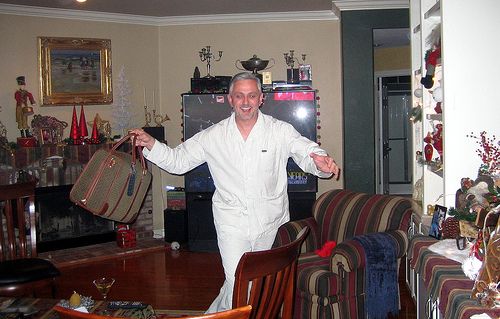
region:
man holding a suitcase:
[73, 73, 343, 226]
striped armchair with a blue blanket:
[315, 193, 410, 317]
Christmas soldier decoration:
[11, 73, 38, 144]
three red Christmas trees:
[70, 103, 100, 146]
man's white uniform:
[215, 145, 282, 220]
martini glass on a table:
[94, 275, 114, 303]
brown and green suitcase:
[77, 134, 150, 222]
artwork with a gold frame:
[39, 37, 112, 102]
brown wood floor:
[138, 254, 209, 297]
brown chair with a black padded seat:
[3, 185, 58, 285]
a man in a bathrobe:
[113, 42, 382, 313]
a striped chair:
[276, 165, 424, 314]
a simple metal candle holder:
[185, 28, 242, 90]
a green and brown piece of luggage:
[61, 106, 188, 248]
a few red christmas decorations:
[66, 98, 110, 153]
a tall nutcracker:
[6, 67, 51, 158]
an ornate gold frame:
[24, 24, 121, 124]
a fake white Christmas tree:
[98, 42, 150, 147]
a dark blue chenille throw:
[328, 213, 420, 313]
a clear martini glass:
[84, 256, 126, 301]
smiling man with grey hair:
[163, 68, 319, 290]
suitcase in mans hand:
[81, 116, 166, 229]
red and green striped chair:
[285, 170, 424, 317]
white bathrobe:
[171, 108, 326, 258]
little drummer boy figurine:
[12, 76, 47, 142]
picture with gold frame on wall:
[29, 31, 129, 125]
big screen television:
[175, 84, 345, 195]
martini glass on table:
[87, 266, 144, 306]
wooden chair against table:
[226, 233, 296, 315]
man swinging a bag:
[59, 48, 358, 295]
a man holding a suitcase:
[67, 70, 342, 265]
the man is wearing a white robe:
[126, 74, 335, 315]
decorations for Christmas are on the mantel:
[5, 70, 167, 150]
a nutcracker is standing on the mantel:
[11, 74, 37, 147]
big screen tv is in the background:
[178, 87, 322, 259]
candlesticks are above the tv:
[190, 40, 315, 92]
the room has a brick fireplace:
[6, 134, 167, 272]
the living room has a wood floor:
[32, 245, 229, 307]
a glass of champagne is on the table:
[91, 271, 121, 316]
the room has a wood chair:
[3, 177, 60, 304]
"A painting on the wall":
[23, 13, 155, 120]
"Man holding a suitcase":
[61, 60, 344, 317]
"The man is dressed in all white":
[138, 68, 357, 311]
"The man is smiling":
[98, 45, 353, 313]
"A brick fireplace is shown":
[0, 136, 181, 281]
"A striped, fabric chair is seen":
[262, 176, 422, 316]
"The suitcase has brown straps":
[74, 128, 187, 228]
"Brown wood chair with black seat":
[3, 172, 70, 303]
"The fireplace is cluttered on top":
[3, 78, 174, 270]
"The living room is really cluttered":
[9, 6, 497, 316]